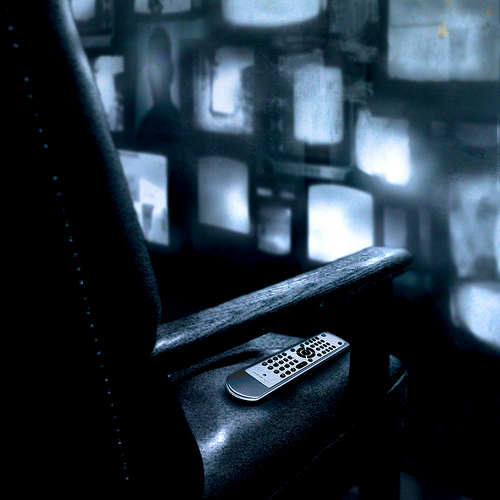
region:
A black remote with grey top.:
[224, 329, 350, 404]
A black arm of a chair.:
[152, 244, 412, 369]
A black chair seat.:
[170, 325, 407, 496]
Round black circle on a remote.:
[300, 347, 311, 356]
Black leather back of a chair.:
[1, 2, 203, 499]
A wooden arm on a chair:
[155, 242, 411, 372]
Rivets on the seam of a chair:
[30, 101, 135, 488]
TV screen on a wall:
[189, 150, 256, 238]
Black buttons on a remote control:
[263, 354, 306, 376]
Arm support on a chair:
[352, 276, 394, 497]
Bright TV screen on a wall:
[349, 106, 429, 197]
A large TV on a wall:
[378, 3, 498, 115]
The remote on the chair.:
[214, 331, 355, 403]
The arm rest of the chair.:
[150, 248, 411, 370]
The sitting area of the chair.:
[152, 308, 409, 485]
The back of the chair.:
[2, 1, 155, 499]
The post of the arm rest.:
[359, 277, 406, 499]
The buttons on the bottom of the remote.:
[265, 350, 303, 382]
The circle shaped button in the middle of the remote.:
[294, 343, 321, 360]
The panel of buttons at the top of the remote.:
[306, 338, 336, 353]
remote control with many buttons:
[221, 328, 351, 404]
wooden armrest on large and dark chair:
[150, 235, 410, 415]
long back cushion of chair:
[5, 5, 200, 495]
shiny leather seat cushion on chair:
[175, 310, 415, 490]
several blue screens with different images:
[67, 0, 496, 352]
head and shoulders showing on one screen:
[129, 17, 186, 147]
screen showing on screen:
[189, 43, 264, 137]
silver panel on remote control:
[220, 327, 346, 406]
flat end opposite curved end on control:
[221, 326, 350, 405]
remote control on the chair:
[227, 316, 355, 396]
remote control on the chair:
[218, 314, 345, 416]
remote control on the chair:
[228, 321, 352, 393]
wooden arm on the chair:
[163, 236, 413, 409]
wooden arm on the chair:
[153, 243, 420, 428]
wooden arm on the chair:
[153, 243, 412, 413]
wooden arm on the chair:
[153, 237, 414, 424]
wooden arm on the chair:
[155, 242, 412, 420]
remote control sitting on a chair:
[226, 328, 348, 400]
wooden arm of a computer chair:
[145, 240, 414, 365]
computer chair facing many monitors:
[3, 3, 419, 491]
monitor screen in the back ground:
[115, 150, 170, 246]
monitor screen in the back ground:
[190, 153, 252, 238]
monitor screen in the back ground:
[255, 200, 290, 253]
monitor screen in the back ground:
[303, 178, 370, 266]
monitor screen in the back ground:
[355, 110, 410, 191]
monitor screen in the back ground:
[286, 61, 346, 149]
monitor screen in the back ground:
[190, 40, 255, 133]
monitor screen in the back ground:
[135, 20, 190, 126]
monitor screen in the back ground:
[385, 2, 497, 82]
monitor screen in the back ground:
[222, 0, 325, 30]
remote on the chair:
[228, 313, 347, 415]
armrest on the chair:
[160, 214, 408, 339]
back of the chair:
[3, 4, 180, 476]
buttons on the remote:
[253, 332, 333, 381]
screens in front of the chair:
[89, 6, 496, 326]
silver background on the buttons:
[238, 330, 339, 382]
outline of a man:
[137, 26, 176, 125]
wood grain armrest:
[153, 225, 396, 330]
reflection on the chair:
[196, 412, 231, 455]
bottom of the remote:
[195, 348, 288, 425]